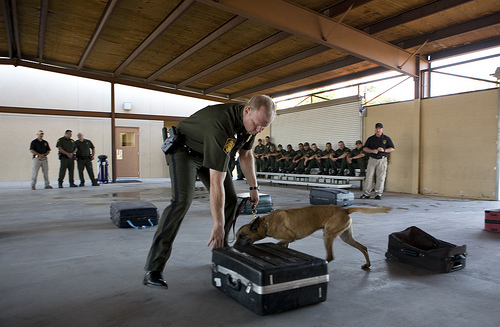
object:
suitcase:
[485, 209, 496, 231]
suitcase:
[384, 224, 469, 274]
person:
[298, 143, 321, 174]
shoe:
[142, 267, 168, 289]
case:
[208, 240, 327, 317]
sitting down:
[299, 143, 321, 174]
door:
[108, 125, 139, 180]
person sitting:
[345, 139, 365, 176]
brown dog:
[236, 203, 373, 269]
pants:
[30, 158, 51, 186]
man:
[29, 129, 53, 189]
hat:
[36, 130, 44, 135]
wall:
[364, 89, 498, 201]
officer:
[138, 95, 278, 288]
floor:
[0, 196, 499, 324]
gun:
[161, 126, 178, 154]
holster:
[161, 139, 173, 153]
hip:
[159, 131, 199, 156]